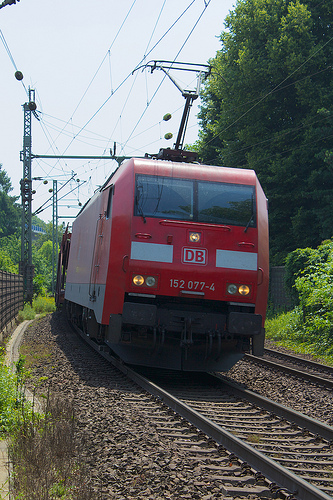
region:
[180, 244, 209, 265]
Deutsche Bahn train logo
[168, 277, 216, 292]
152 077-4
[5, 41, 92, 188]
electric train overhead catenary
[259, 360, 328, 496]
2 railroad tracks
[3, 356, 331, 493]
1 railroad track bed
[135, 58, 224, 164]
pantograph conducts electricity from catenary to train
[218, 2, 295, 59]
Deciduous tree's green leaves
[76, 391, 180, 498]
gravel filled train bed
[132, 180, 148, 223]
train window windshield wiper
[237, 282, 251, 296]
locomotive headlamp is on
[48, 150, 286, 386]
a red train on rails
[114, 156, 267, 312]
front of train is red and white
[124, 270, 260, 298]
train has four headlights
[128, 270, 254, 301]
two headlights are turn on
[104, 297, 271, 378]
bumper of train is black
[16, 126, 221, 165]
wires crossing above the train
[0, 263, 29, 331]
a fence on left side of rails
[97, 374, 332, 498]
rails are metal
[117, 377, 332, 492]
base of rails are wood planks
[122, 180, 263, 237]
wipes on side of windshields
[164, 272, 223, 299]
the numbers are white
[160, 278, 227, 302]
numbers on the train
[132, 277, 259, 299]
lights on the train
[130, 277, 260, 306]
the lights are orange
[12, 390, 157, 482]
grass beside the gravel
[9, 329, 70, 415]
dirt beside the gravel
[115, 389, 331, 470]
gravel under the tracks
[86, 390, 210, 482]
the gravel is gray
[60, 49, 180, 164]
wires above the train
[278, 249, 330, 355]
bushes in the grass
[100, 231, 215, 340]
the train is red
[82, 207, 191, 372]
the train is red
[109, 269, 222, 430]
the train is red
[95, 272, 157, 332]
the train is red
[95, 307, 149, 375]
the train is red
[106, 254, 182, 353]
the train is red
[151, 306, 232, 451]
the train is red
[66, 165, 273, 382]
a train powered by electricity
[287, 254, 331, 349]
a green bush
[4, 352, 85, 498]
a different kinds of weed.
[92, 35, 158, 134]
electrical wires that generates power to trains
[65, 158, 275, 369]
a red train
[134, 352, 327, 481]
two rails for trains side by side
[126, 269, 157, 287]
signal light on the face of the train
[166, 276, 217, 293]
a train number tag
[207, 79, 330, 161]
high trees are along the train tracks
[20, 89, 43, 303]
a metal pole holding the electrical lines for the train